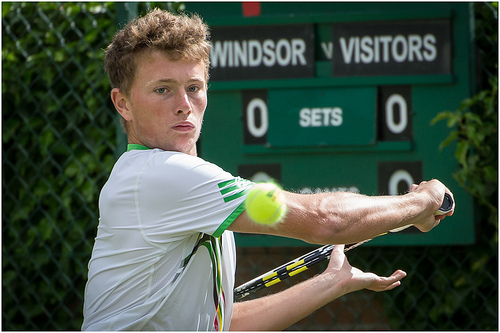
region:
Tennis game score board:
[205, 10, 490, 180]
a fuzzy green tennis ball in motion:
[240, 160, 291, 230]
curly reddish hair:
[100, 1, 210, 71]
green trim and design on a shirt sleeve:
[205, 166, 245, 247]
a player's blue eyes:
[140, 65, 212, 100]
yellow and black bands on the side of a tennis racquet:
[232, 241, 349, 288]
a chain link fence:
[7, 1, 72, 81]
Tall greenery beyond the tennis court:
[5, 40, 95, 330]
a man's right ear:
[109, 77, 140, 133]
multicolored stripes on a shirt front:
[200, 276, 235, 328]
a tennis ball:
[235, 174, 315, 231]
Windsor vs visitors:
[222, 31, 471, 81]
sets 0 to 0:
[235, 86, 425, 142]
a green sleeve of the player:
[190, 177, 252, 234]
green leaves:
[18, 29, 87, 243]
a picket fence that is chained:
[23, 33, 85, 247]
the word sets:
[292, 106, 377, 150]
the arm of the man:
[302, 191, 469, 236]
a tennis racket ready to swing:
[233, 250, 355, 300]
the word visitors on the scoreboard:
[330, 30, 447, 80]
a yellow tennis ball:
[232, 162, 306, 234]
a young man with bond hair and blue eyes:
[88, 24, 239, 151]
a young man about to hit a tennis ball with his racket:
[84, 27, 469, 329]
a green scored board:
[201, 4, 498, 249]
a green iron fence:
[3, 3, 92, 322]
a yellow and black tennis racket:
[239, 203, 489, 299]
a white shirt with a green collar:
[84, 134, 278, 331]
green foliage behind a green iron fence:
[3, 5, 115, 328]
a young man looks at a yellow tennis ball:
[66, 10, 453, 331]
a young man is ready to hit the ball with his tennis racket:
[41, 2, 481, 326]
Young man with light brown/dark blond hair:
[82, 8, 460, 331]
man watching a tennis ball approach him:
[69, 8, 459, 331]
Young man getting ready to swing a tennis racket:
[82, 4, 457, 331]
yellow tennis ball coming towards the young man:
[244, 179, 288, 229]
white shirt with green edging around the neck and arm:
[72, 137, 269, 332]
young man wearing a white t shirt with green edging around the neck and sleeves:
[76, 1, 467, 331]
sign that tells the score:
[207, 12, 479, 243]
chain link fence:
[6, 16, 96, 311]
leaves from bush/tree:
[435, 48, 496, 294]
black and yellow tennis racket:
[227, 188, 455, 302]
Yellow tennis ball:
[237, 172, 290, 232]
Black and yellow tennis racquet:
[229, 193, 446, 288]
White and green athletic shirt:
[82, 149, 240, 331]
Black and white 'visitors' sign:
[333, 27, 450, 77]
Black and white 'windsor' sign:
[204, 23, 315, 80]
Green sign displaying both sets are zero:
[211, 81, 448, 146]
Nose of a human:
[169, 91, 196, 121]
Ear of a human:
[103, 88, 138, 125]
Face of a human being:
[98, 8, 226, 147]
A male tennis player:
[61, 13, 443, 330]